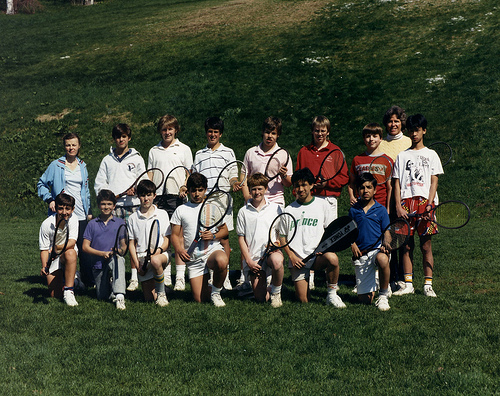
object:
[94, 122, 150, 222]
boy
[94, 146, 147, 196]
hoodie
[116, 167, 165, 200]
tennis racket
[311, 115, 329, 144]
head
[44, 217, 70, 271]
tennis racket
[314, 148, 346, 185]
tennis racket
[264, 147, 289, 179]
tennis racket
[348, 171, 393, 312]
boy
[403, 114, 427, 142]
head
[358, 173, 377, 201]
head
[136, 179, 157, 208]
head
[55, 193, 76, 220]
head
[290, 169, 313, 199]
head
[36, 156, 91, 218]
jacket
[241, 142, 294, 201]
pink shirt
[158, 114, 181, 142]
head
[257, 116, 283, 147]
head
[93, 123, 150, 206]
boy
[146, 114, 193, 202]
boy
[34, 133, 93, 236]
coach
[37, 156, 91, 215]
blue sweater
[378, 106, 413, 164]
lady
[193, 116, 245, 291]
boy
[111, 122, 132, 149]
head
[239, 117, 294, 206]
boy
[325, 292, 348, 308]
shoes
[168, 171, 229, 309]
boys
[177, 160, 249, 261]
rackets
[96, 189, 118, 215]
head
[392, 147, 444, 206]
shirt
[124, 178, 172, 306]
boy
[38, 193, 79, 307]
boy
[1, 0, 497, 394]
grass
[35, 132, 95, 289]
woman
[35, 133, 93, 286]
person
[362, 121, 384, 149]
head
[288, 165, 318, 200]
head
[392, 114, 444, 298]
boy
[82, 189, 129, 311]
boy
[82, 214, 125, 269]
shirt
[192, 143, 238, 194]
striped shirt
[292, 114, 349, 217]
boy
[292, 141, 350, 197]
shirt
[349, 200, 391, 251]
shirt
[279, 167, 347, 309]
boy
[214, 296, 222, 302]
laces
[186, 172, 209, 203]
head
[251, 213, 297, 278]
racket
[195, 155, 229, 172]
stripes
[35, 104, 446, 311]
team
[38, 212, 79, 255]
shirt